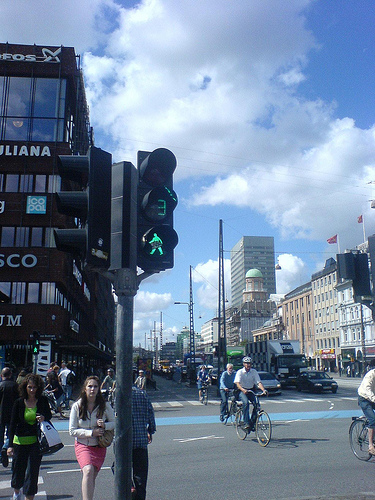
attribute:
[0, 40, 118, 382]
building — brown, white, multistory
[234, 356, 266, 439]
man — old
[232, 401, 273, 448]
bike — white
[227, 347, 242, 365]
truck — semi truck, black, white, checkered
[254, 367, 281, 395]
car — silver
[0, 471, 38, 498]
crosswalk — white, painted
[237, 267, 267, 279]
dome — green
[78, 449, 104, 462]
skirt — pink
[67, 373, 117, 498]
woman — young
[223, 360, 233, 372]
hair — white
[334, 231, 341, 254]
pole — white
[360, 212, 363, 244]
pole — white